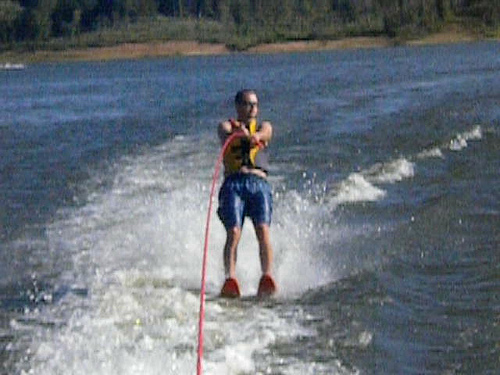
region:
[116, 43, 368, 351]
a man that is skiing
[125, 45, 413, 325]
a man that is water skiing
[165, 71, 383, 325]
a man wearing a jacket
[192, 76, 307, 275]
a man wearing a life jacket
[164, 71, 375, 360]
a man holding a rope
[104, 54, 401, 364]
a body of blue water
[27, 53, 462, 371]
a body of water that is blue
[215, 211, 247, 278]
leg of a person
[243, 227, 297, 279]
leg of a person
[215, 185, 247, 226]
thigh of a person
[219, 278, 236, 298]
feet of a person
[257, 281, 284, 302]
feet of a person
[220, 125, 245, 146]
arm of a person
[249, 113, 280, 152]
arm of a person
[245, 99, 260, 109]
nose of a person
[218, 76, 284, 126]
head of the man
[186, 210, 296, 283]
legs of the man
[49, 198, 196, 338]
water under the man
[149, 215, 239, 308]
rope in the water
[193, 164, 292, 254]
blue shorts on man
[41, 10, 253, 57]
tree in the distance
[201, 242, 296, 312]
objects on man's feet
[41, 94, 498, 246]
wake of a water skier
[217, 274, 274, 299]
red water skis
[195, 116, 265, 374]
a red tow line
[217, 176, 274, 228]
blue swim trunks on skier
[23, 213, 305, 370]
the rough water made by the motor boat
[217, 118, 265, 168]
man wears a yellow life jacket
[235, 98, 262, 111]
skier wearing eyeglasses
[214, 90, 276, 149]
skier looks off to his left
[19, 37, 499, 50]
sand on the beach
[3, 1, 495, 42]
dense vegetaion on the beach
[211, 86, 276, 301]
a man is on skis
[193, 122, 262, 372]
a red ski rope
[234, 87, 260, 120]
head of a man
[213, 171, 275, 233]
a man's blue shorts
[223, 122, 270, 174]
a lifejacket on a man's chest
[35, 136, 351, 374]
the wake from a boat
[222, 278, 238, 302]
a red ski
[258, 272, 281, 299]
a red water ski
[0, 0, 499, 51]
foliage on the shoreline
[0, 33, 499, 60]
dirt on the shoreline